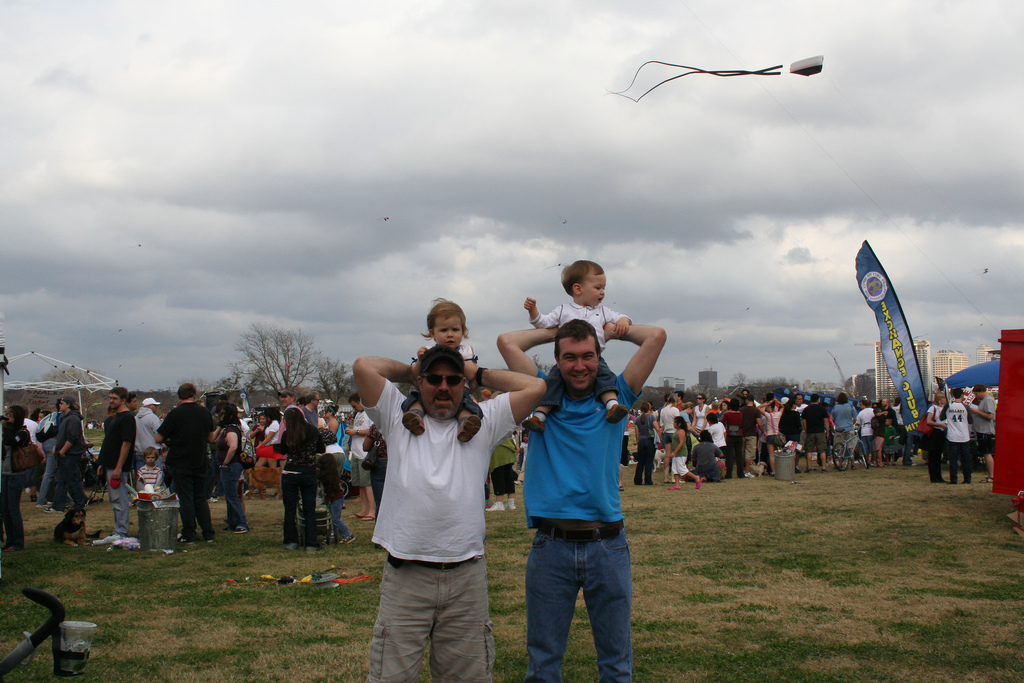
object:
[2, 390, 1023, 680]
field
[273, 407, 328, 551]
person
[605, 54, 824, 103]
kite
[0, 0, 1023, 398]
sky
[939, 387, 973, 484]
person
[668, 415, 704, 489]
person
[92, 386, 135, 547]
person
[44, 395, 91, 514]
person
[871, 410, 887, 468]
person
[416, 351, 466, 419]
head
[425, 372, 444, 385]
glasses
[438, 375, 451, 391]
nose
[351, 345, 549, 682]
man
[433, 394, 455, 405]
mouth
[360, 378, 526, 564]
shirt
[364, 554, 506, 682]
pants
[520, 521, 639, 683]
jeans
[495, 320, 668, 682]
man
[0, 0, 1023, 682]
festival